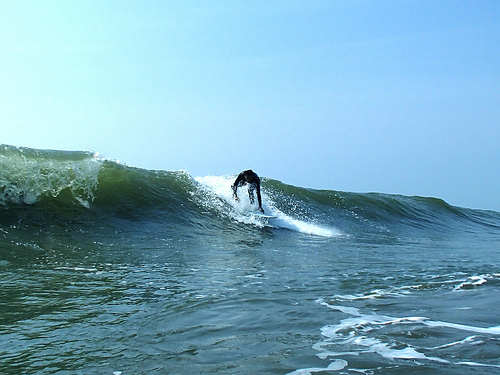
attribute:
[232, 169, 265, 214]
man — crouched, surfing, bending down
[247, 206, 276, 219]
surfboard — white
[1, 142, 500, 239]
wave — breaking, curling, blue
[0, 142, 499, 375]
water — splashing, white, blue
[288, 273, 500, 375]
foam — white, calm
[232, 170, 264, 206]
wetsuit — black, dark-colored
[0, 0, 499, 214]
sky — pristine, cloudless, blue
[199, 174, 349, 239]
splash — white